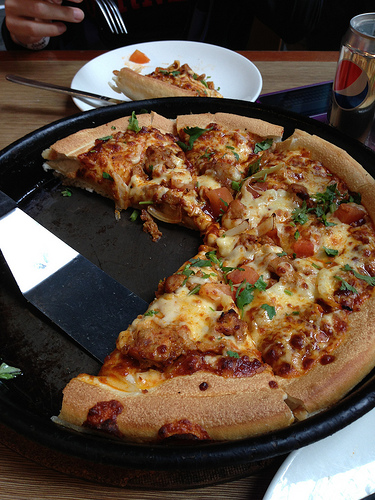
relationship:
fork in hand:
[93, 1, 131, 37] [3, 0, 85, 51]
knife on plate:
[4, 70, 126, 104] [69, 38, 265, 111]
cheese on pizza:
[161, 291, 199, 327] [42, 110, 374, 444]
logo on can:
[334, 60, 370, 113] [325, 10, 375, 154]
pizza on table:
[42, 110, 374, 444] [0, 49, 374, 500]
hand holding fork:
[3, 0, 85, 51] [93, 1, 131, 37]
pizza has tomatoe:
[42, 110, 374, 444] [291, 235, 314, 258]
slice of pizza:
[40, 107, 214, 234] [42, 110, 374, 444]